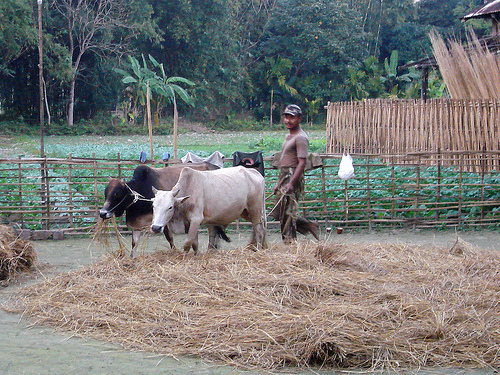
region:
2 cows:
[83, 154, 288, 243]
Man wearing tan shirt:
[261, 98, 325, 238]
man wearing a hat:
[274, 95, 324, 138]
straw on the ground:
[51, 250, 497, 367]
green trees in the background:
[41, 60, 423, 108]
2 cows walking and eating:
[63, 145, 283, 285]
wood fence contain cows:
[13, 130, 496, 222]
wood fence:
[313, 85, 411, 135]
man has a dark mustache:
[273, 98, 315, 145]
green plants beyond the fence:
[15, 135, 480, 213]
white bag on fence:
[331, 150, 361, 188]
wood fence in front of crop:
[365, 142, 490, 212]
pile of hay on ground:
[96, 235, 481, 352]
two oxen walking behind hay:
[95, 157, 273, 255]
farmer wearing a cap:
[265, 93, 321, 248]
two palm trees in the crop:
[110, 45, 192, 161]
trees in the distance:
[211, 18, 361, 69]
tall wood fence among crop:
[315, 93, 497, 164]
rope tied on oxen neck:
[127, 180, 162, 205]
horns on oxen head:
[145, 185, 187, 195]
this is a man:
[267, 101, 324, 226]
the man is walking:
[278, 104, 315, 236]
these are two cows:
[98, 156, 265, 252]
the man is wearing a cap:
[286, 106, 301, 113]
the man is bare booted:
[305, 211, 330, 238]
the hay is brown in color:
[140, 259, 445, 355]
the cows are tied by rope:
[125, 191, 152, 209]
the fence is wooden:
[328, 98, 498, 158]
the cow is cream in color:
[187, 172, 259, 247]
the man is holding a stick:
[271, 181, 292, 210]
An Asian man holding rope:
[273, 104, 339, 251]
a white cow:
[155, 167, 277, 252]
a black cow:
[99, 166, 154, 236]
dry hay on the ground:
[59, 246, 486, 369]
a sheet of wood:
[319, 94, 497, 171]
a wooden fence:
[3, 151, 104, 238]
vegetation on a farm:
[361, 144, 495, 220]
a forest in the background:
[56, 19, 374, 116]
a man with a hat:
[280, 108, 306, 137]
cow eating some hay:
[91, 167, 135, 267]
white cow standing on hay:
[148, 162, 267, 264]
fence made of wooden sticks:
[325, 99, 499, 171]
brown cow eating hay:
[88, 163, 149, 253]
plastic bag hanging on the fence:
[330, 151, 366, 222]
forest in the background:
[203, 41, 277, 122]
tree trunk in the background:
[24, 33, 55, 133]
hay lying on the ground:
[123, 261, 304, 334]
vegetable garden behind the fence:
[16, 146, 94, 217]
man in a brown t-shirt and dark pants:
[273, 103, 314, 246]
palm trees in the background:
[111, 51, 197, 113]